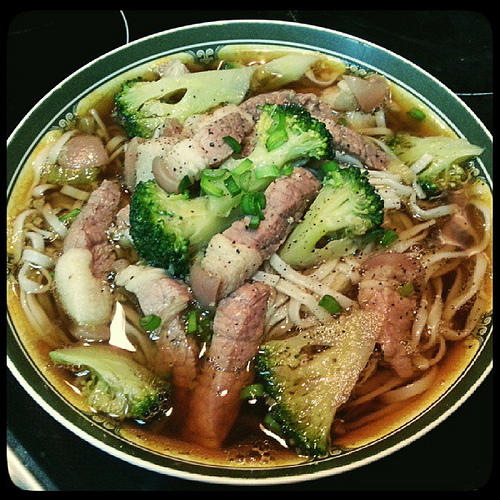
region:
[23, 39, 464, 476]
this is an asian meal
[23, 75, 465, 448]
the soup is asian style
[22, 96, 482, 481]
the broccoli is green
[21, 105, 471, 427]
wide rice noodles in broth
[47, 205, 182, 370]
the white cauliflower florets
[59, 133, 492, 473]
the meat is red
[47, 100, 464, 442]
the soup has brown broth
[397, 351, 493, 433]
the rim of the bowl is green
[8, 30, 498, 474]
spring onions on the center of the meal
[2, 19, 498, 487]
Steak and vegetable soup in bowl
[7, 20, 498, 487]
White bowl with green trim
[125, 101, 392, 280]
Steamed broccoli in soup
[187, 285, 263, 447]
Cooked steak in soup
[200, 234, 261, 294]
White fat on steak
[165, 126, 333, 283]
Black seasonsing on meat and vegetables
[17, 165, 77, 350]
White noodles in soup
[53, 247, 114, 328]
Water chestnut in soup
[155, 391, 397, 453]
Brown broth of soup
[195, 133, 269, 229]
Chopped onion in soup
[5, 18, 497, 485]
a bowl of chinese food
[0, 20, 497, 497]
a bowl of beef and broccoli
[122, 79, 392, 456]
broccoli florets in a dish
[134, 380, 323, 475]
brown sauce in a bowl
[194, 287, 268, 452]
a piece of sliced beef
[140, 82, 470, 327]
black pepper sprinkled on beef and broccoli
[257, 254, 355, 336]
a section of egg noodles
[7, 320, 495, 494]
the blue and white rim of the bowl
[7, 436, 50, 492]
a silver portion of a fork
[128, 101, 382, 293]
green broccoli in the middle of the bowl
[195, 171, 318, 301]
a piece of pork with fat meat on the end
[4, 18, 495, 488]
a round bowl with a green rim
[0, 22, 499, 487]
a bowl with noodles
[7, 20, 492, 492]
a brown broth is in the bowl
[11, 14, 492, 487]
a white bowl with a green accent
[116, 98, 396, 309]
black peppers sprinkled on top of the soup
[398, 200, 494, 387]
noodles under the broth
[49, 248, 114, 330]
a large piece of white colored fat meat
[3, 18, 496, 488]
bowl of Asian-inspired soup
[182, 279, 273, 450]
strip of meat in soup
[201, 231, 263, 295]
piece of fat on meat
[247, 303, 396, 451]
chunk of broccoli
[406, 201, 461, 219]
a strip of Asian noodle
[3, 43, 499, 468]
broth with vegetables, noodles, and meat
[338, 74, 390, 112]
piece of onion in soup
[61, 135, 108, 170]
piece of mushroom in soup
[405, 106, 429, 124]
piece of chive floating in broth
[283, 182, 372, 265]
green brocolli in a bowl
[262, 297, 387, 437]
green brocolli in a bowl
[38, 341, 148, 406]
green brocolli in a bowl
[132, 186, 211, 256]
green brocolli in a bowl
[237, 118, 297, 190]
green brocolli in a bowl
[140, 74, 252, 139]
green brocolli in a bowl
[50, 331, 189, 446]
green brocolli in a bowl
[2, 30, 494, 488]
a dish of food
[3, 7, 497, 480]
food on a plate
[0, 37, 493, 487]
a bowl of food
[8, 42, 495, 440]
meat and veggies on plate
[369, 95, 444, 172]
the juice is tan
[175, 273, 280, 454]
meat in the juice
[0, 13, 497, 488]
the dish is cooked